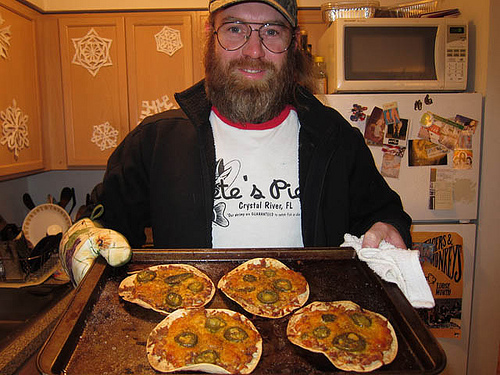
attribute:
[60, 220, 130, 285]
mitt — in the picture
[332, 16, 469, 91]
microwave — white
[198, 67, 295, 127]
beard — in the picture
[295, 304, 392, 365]
toppings — in the picture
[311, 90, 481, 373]
refrigerator freezer — in the picture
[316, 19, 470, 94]
microwave — small, white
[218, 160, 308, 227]
words — in the picture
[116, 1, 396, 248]
person — in the picture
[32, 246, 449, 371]
cookie sheet — in the picture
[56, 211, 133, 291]
oven mit — in the picture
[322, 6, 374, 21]
food tray — in the picture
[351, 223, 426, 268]
hand — in the picture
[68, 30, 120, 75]
snowflake — white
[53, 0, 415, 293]
person — in the picture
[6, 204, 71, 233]
plate — in the picture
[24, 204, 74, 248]
dish — in the picture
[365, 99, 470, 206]
items — in the picture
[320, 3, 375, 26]
container — in the picture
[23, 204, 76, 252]
plate — in the picture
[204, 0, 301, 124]
head — in the picture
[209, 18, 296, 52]
glasses — eye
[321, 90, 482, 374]
fridge — in the picture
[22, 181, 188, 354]
potholder — in the picture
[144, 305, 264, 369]
pizza — in the picture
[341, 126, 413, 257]
arm — in the picture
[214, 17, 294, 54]
glasses — in the picture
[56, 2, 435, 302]
man — in the picture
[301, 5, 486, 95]
microwave — in the picture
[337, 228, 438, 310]
kitchen towel — white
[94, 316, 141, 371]
pan — in the picture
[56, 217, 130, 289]
glove — green , orange 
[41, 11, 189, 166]
decorations — lacy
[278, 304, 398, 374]
pizza — small  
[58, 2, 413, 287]
man — four